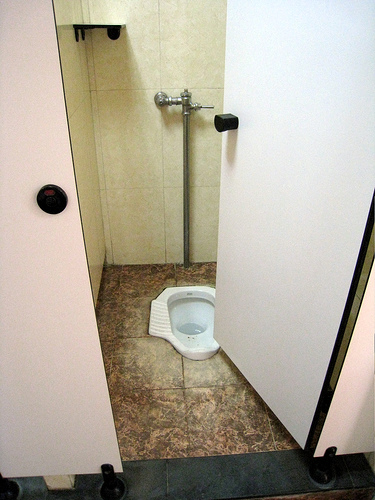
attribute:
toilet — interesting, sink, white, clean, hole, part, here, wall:
[143, 286, 226, 356]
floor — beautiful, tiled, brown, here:
[107, 270, 312, 486]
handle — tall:
[192, 102, 217, 114]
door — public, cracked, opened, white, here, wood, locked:
[210, 3, 373, 456]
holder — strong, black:
[74, 23, 124, 46]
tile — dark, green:
[108, 386, 187, 458]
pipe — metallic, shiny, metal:
[182, 106, 193, 276]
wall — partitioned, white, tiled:
[53, 5, 131, 310]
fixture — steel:
[152, 89, 177, 110]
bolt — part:
[34, 185, 71, 216]